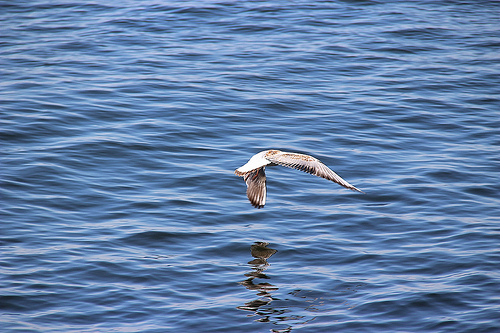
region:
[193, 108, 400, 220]
a seagull flying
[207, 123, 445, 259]
the bird has its wings spread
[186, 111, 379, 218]
the bird is low to the water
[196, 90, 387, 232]
the bird is flying directly above the water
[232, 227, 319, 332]
this is the reflection of the bird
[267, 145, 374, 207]
the bird has grey and black feathers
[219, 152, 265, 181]
the bird's tail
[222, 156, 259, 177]
tail feathers of the bird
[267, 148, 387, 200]
this is a wing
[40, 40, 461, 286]
the water is a deep and dark blue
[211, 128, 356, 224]
seagull flying over water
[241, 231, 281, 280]
reflection of seagull in water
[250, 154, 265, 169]
white tail fin of bird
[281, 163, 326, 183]
black wing tips of bird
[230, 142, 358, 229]
bird flying in air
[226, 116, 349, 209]
seagull flying in the air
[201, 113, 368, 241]
bird flying over the ocean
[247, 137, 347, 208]
bird flying over ripples in water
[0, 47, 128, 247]
ripples in the water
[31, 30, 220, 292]
small waves in the water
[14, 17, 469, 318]
a beautiful image of the sea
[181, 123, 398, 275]
a bird soaring over the water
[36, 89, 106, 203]
calm glassy sea water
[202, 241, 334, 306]
the reflection of a bird in the water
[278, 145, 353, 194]
the extended wing of a bird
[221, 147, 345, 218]
a wild animal hunting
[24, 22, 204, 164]
very deep blue water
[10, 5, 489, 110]
ripples traveling through sea water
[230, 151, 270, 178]
the white feathered back of a bird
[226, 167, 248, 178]
brown feathers on a birds tail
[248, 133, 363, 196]
bird soaring in the air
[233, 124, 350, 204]
bird flying in the sky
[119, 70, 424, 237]
bird flying over crystal blue water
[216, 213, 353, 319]
reflection of bird in the water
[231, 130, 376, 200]
bird with two large wings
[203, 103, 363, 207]
bird heading toward the water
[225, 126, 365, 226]
large white bird flying over water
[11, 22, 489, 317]
A bird is flying over the water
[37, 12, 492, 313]
The bird is hunting for fish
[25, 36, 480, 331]
The bird is watching for predators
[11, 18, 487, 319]
The bird is close to the shore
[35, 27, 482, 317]
The bird has a large wingspan